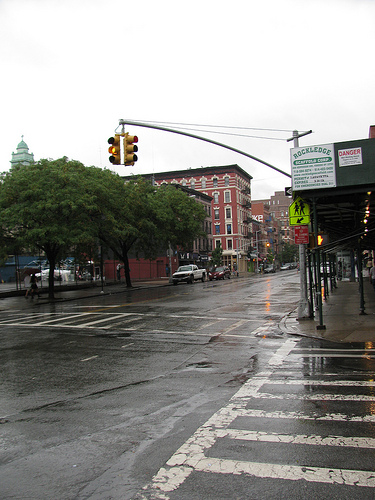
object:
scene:
[0, 9, 373, 499]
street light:
[107, 134, 120, 166]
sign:
[290, 143, 337, 190]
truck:
[172, 264, 208, 285]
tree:
[0, 153, 210, 299]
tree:
[208, 242, 223, 267]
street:
[0, 272, 375, 499]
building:
[77, 164, 255, 279]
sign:
[288, 194, 311, 227]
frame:
[224, 189, 232, 203]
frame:
[224, 204, 233, 222]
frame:
[225, 222, 233, 234]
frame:
[226, 237, 233, 251]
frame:
[214, 238, 222, 253]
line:
[264, 379, 375, 388]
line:
[238, 408, 374, 424]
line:
[218, 428, 375, 450]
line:
[193, 457, 375, 489]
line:
[135, 338, 301, 499]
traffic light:
[122, 132, 139, 167]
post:
[118, 118, 292, 178]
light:
[108, 144, 120, 156]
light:
[128, 135, 139, 143]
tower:
[9, 133, 36, 169]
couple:
[30, 274, 42, 299]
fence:
[0, 254, 178, 291]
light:
[267, 242, 271, 247]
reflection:
[265, 278, 270, 313]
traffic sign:
[293, 226, 309, 245]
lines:
[80, 355, 98, 362]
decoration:
[154, 174, 251, 198]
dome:
[16, 140, 28, 149]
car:
[209, 265, 231, 281]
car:
[264, 264, 275, 273]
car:
[280, 262, 296, 270]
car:
[320, 261, 334, 273]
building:
[251, 191, 293, 254]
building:
[369, 124, 375, 138]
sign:
[338, 147, 363, 167]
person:
[165, 263, 169, 277]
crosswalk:
[0, 304, 274, 338]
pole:
[292, 130, 311, 319]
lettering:
[292, 147, 334, 188]